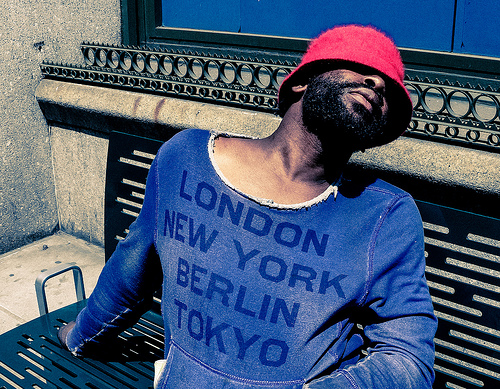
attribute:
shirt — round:
[45, 148, 474, 387]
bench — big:
[0, 125, 187, 386]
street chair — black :
[428, 209, 490, 361]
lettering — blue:
[300, 228, 330, 256]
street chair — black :
[415, 182, 499, 385]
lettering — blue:
[158, 175, 407, 300]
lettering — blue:
[299, 226, 334, 256]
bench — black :
[6, 127, 166, 387]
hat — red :
[246, 15, 441, 139]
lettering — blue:
[159, 167, 345, 370]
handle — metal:
[35, 272, 73, 305]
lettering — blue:
[279, 252, 361, 302]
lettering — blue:
[202, 315, 228, 356]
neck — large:
[197, 115, 365, 235]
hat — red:
[275, 24, 412, 146]